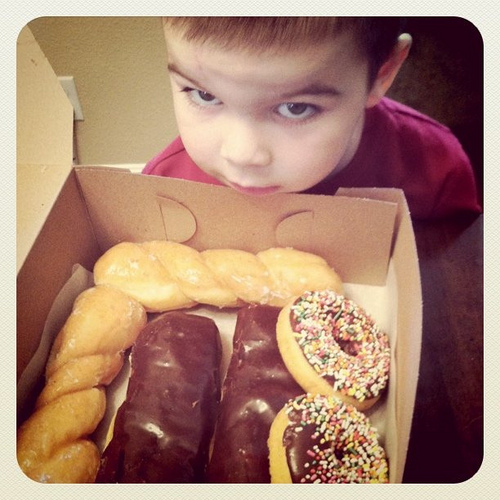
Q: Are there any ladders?
A: No, there are no ladders.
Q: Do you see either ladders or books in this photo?
A: No, there are no ladders or books.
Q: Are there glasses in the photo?
A: No, there are no glasses.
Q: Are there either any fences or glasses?
A: No, there are no glasses or fences.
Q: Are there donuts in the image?
A: Yes, there are donuts.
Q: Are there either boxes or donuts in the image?
A: Yes, there are donuts.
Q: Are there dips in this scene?
A: No, there are no dips.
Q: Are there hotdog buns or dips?
A: No, there are no dips or hotdog buns.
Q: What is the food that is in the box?
A: The food is donuts.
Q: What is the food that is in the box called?
A: The food is donuts.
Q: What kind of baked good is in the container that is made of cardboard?
A: The food is donuts.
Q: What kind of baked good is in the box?
A: The food is donuts.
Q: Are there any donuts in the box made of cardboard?
A: Yes, there are donuts in the box.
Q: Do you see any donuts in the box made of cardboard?
A: Yes, there are donuts in the box.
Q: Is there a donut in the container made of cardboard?
A: Yes, there are donuts in the box.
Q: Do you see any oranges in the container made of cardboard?
A: No, there are donuts in the box.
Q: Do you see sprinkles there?
A: Yes, there are sprinkles.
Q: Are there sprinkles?
A: Yes, there are sprinkles.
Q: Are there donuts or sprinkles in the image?
A: Yes, there are sprinkles.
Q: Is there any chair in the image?
A: No, there are no chairs.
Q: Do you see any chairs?
A: No, there are no chairs.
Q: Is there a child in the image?
A: Yes, there is a child.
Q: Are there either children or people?
A: Yes, there is a child.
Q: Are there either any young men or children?
A: Yes, there is a young child.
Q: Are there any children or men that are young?
A: Yes, the child is young.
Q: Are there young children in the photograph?
A: Yes, there is a young child.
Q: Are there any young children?
A: Yes, there is a young child.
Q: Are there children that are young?
A: Yes, there is a child that is young.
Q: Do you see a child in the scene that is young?
A: Yes, there is a child that is young.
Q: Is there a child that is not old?
A: Yes, there is an young child.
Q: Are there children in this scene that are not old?
A: Yes, there is an young child.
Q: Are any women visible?
A: No, there are no women.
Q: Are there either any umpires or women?
A: No, there are no women or umpires.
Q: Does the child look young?
A: Yes, the child is young.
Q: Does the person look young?
A: Yes, the child is young.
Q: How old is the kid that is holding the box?
A: The kid is young.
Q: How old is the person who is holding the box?
A: The kid is young.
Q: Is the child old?
A: No, the child is young.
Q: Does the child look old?
A: No, the child is young.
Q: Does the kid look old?
A: No, the kid is young.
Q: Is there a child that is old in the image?
A: No, there is a child but he is young.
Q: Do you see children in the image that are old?
A: No, there is a child but he is young.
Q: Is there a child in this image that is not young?
A: No, there is a child but he is young.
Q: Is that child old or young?
A: The child is young.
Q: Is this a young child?
A: Yes, this is a young child.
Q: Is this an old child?
A: No, this is a young child.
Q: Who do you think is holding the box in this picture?
A: The kid is holding the box.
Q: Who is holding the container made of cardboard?
A: The kid is holding the box.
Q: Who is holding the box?
A: The kid is holding the box.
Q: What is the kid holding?
A: The kid is holding the box.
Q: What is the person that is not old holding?
A: The kid is holding the box.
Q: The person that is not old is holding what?
A: The kid is holding the box.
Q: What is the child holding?
A: The kid is holding the box.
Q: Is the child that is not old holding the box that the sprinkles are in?
A: Yes, the kid is holding the box.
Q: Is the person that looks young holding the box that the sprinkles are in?
A: Yes, the kid is holding the box.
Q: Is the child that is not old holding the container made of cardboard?
A: Yes, the kid is holding the box.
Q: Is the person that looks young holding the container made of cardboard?
A: Yes, the kid is holding the box.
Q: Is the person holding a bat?
A: No, the child is holding the box.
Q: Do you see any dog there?
A: No, there are no dogs.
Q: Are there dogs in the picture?
A: No, there are no dogs.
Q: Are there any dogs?
A: No, there are no dogs.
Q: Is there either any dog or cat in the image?
A: No, there are no dogs or cats.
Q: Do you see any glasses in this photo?
A: No, there are no glasses.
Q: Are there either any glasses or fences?
A: No, there are no glasses or fences.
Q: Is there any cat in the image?
A: No, there are no cats.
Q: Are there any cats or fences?
A: No, there are no cats or fences.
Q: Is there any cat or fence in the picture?
A: No, there are no cats or fences.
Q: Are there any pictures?
A: No, there are no pictures.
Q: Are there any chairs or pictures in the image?
A: No, there are no pictures or chairs.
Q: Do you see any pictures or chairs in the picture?
A: No, there are no pictures or chairs.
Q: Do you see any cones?
A: No, there are no cones.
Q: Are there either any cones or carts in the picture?
A: No, there are no cones or carts.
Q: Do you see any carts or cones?
A: No, there are no cones or carts.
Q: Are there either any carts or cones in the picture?
A: No, there are no cones or carts.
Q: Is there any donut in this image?
A: Yes, there is a donut.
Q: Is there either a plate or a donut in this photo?
A: Yes, there is a donut.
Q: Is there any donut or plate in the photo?
A: Yes, there is a donut.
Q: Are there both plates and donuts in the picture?
A: No, there is a donut but no plates.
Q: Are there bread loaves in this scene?
A: No, there are no bread loaves.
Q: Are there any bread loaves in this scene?
A: No, there are no bread loaves.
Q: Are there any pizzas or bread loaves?
A: No, there are no bread loaves or pizzas.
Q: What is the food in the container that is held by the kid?
A: The food is a donut.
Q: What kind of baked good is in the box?
A: The food is a donut.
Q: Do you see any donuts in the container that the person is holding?
A: Yes, there is a donut in the box.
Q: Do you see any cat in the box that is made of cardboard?
A: No, there is a donut in the box.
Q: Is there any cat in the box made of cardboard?
A: No, there is a donut in the box.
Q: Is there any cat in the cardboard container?
A: No, there is a donut in the box.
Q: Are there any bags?
A: No, there are no bags.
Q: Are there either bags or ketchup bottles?
A: No, there are no bags or ketchup bottles.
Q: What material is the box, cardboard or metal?
A: The box is made of cardboard.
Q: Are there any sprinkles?
A: Yes, there are sprinkles.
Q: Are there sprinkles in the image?
A: Yes, there are sprinkles.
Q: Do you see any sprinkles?
A: Yes, there are sprinkles.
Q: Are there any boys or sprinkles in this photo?
A: Yes, there are sprinkles.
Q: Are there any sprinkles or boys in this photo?
A: Yes, there are sprinkles.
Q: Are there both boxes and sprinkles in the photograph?
A: Yes, there are both sprinkles and a box.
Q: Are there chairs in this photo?
A: No, there are no chairs.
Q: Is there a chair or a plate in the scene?
A: No, there are no chairs or plates.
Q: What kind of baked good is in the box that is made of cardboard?
A: The food is a pastry.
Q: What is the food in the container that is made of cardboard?
A: The food is a pastry.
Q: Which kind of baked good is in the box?
A: The food is a pastry.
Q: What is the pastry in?
A: The pastry is in the box.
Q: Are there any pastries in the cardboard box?
A: Yes, there is a pastry in the box.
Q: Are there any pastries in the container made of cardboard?
A: Yes, there is a pastry in the box.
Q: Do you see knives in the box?
A: No, there is a pastry in the box.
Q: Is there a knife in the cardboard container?
A: No, there is a pastry in the box.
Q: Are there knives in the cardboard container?
A: No, there is a pastry in the box.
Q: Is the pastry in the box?
A: Yes, the pastry is in the box.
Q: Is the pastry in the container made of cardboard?
A: Yes, the pastry is in the box.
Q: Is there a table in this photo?
A: Yes, there is a table.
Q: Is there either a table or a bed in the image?
A: Yes, there is a table.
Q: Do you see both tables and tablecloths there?
A: No, there is a table but no tablecloths.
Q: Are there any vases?
A: No, there are no vases.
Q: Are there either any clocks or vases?
A: No, there are no vases or clocks.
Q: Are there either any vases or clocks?
A: No, there are no vases or clocks.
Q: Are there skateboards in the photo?
A: No, there are no skateboards.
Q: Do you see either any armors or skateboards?
A: No, there are no skateboards or armors.